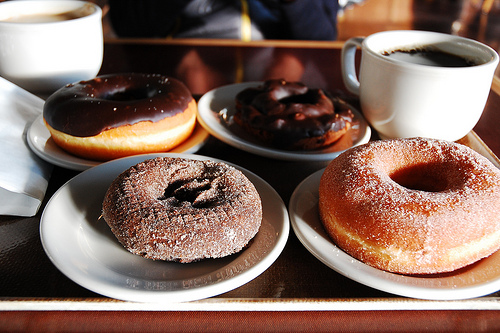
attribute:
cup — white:
[340, 26, 498, 140]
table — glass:
[0, 40, 499, 332]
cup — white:
[2, 0, 105, 91]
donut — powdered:
[104, 156, 262, 260]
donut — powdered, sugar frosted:
[318, 137, 499, 274]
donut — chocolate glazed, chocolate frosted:
[45, 72, 197, 158]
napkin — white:
[1, 77, 52, 218]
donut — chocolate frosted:
[233, 79, 356, 148]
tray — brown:
[1, 93, 499, 311]